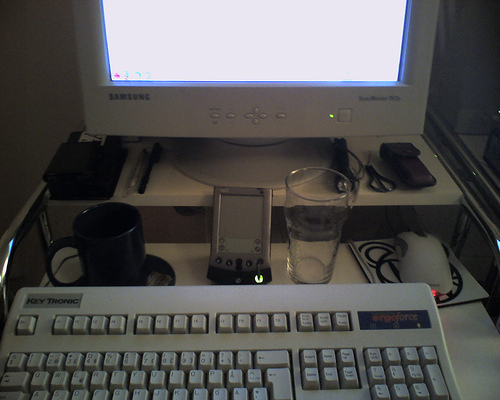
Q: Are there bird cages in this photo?
A: No, there are no bird cages.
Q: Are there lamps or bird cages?
A: No, there are no bird cages or lamps.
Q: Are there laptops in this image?
A: Yes, there is a laptop.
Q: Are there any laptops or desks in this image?
A: Yes, there is a laptop.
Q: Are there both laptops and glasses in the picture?
A: Yes, there are both a laptop and glasses.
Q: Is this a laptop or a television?
A: This is a laptop.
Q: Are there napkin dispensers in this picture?
A: No, there are no napkin dispensers.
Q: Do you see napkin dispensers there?
A: No, there are no napkin dispensers.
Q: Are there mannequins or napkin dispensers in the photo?
A: No, there are no napkin dispensers or mannequins.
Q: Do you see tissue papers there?
A: No, there are no tissue papers.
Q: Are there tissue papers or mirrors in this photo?
A: No, there are no tissue papers or mirrors.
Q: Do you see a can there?
A: No, there are no cans.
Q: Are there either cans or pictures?
A: No, there are no cans or pictures.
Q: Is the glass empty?
A: Yes, the glass is empty.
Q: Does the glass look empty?
A: Yes, the glass is empty.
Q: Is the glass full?
A: No, the glass is empty.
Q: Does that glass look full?
A: No, the glass is empty.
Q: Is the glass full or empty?
A: The glass is empty.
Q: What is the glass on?
A: The glass is on the desk.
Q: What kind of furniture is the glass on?
A: The glass is on the desk.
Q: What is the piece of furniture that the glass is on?
A: The piece of furniture is a desk.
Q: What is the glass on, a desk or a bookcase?
A: The glass is on a desk.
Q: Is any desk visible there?
A: Yes, there is a desk.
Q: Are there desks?
A: Yes, there is a desk.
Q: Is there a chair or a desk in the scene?
A: Yes, there is a desk.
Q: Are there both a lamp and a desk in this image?
A: No, there is a desk but no lamps.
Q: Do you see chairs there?
A: No, there are no chairs.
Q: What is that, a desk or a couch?
A: That is a desk.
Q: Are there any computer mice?
A: Yes, there is a computer mouse.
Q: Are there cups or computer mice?
A: Yes, there is a computer mouse.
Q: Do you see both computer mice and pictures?
A: No, there is a computer mouse but no pictures.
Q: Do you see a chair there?
A: No, there are no chairs.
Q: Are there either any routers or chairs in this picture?
A: No, there are no chairs or routers.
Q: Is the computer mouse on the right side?
A: Yes, the computer mouse is on the right of the image.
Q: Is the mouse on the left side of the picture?
A: No, the mouse is on the right of the image.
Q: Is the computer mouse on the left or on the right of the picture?
A: The computer mouse is on the right of the image.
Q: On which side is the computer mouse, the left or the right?
A: The computer mouse is on the right of the image.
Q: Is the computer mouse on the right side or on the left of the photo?
A: The computer mouse is on the right of the image.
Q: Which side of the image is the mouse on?
A: The mouse is on the right of the image.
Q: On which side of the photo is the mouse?
A: The mouse is on the right of the image.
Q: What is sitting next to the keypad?
A: The mouse is sitting next to the keypad.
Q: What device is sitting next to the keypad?
A: The device is a computer mouse.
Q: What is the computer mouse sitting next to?
A: The computer mouse is sitting next to the keypad.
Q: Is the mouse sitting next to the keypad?
A: Yes, the mouse is sitting next to the keypad.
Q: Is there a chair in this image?
A: No, there are no chairs.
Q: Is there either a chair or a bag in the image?
A: No, there are no chairs or bags.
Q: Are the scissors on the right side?
A: Yes, the scissors are on the right of the image.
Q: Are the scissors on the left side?
A: No, the scissors are on the right of the image.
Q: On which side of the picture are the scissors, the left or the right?
A: The scissors are on the right of the image.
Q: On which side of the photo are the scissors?
A: The scissors are on the right of the image.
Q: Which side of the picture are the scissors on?
A: The scissors are on the right of the image.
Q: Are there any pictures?
A: No, there are no pictures.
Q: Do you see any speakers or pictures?
A: No, there are no pictures or speakers.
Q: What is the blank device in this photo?
A: The device is a screen.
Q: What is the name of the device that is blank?
A: The device is a screen.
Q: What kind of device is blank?
A: The device is a screen.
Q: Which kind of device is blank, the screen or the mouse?
A: The screen is blank.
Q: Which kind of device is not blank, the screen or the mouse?
A: The mouse is not blank.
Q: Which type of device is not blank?
A: The device is a computer mouse.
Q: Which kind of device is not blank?
A: The device is a computer mouse.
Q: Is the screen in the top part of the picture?
A: Yes, the screen is in the top of the image.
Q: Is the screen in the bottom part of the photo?
A: No, the screen is in the top of the image.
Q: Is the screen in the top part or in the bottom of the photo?
A: The screen is in the top of the image.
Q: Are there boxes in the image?
A: No, there are no boxes.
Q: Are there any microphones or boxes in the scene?
A: No, there are no boxes or microphones.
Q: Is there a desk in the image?
A: Yes, there is a desk.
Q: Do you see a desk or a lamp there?
A: Yes, there is a desk.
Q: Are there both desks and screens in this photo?
A: Yes, there are both a desk and a screen.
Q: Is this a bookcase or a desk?
A: This is a desk.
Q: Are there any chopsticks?
A: No, there are no chopsticks.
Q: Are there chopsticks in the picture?
A: No, there are no chopsticks.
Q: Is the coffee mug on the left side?
A: Yes, the coffee mug is on the left of the image.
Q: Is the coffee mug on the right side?
A: No, the coffee mug is on the left of the image.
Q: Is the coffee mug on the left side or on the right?
A: The coffee mug is on the left of the image.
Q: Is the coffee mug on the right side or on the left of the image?
A: The coffee mug is on the left of the image.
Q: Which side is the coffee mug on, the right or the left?
A: The coffee mug is on the left of the image.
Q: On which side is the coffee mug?
A: The coffee mug is on the left of the image.